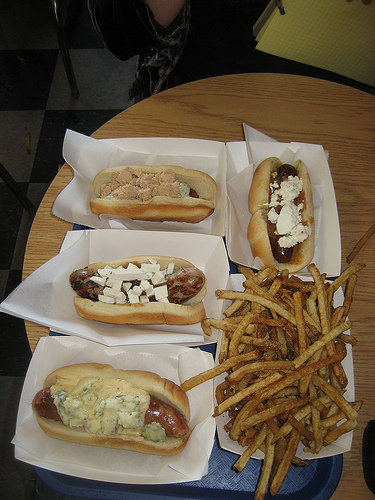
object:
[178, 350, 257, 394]
french fries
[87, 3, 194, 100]
black shirt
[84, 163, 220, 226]
hotdog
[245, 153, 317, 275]
hotdog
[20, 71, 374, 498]
table top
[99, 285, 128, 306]
wood grain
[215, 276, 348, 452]
mountains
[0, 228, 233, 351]
tray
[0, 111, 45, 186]
tile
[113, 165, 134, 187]
food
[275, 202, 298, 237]
food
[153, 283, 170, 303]
food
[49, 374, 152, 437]
food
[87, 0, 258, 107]
person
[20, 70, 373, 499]
table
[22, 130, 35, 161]
garbage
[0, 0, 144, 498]
ground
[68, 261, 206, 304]
brat/toppings/bun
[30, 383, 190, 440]
brat/toppings/bun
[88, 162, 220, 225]
brat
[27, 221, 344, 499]
blue tray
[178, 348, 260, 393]
french fry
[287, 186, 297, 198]
garnish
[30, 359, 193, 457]
bun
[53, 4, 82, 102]
chair leg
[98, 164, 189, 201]
topping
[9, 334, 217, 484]
paper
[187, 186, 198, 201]
brat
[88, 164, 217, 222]
bun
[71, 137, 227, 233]
paper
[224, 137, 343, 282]
container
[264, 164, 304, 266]
brat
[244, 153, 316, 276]
bun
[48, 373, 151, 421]
toppings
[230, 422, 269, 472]
fries